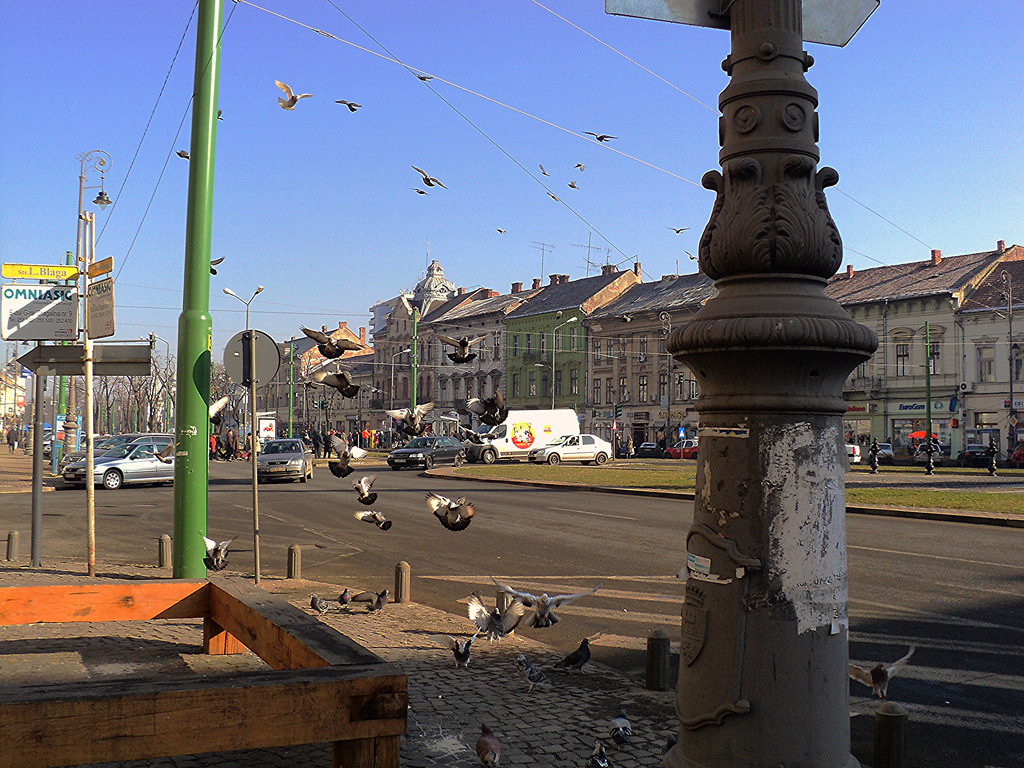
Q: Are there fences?
A: No, there are no fences.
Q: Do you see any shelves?
A: No, there are no shelves.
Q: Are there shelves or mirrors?
A: No, there are no shelves or mirrors.